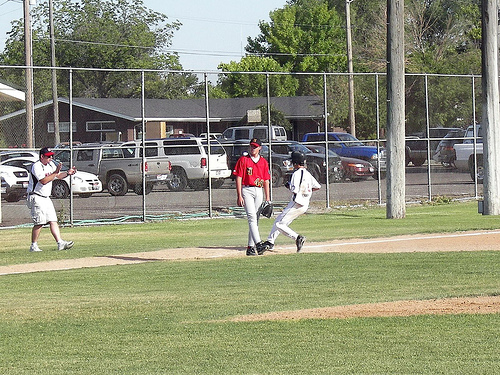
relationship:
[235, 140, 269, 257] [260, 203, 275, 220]
person playing with baseball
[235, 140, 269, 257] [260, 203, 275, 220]
player of baseball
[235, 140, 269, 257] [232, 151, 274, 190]
player wearing a red shirt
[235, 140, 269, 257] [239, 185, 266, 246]
player has a white pants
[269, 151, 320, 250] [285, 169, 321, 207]
player has a white shirt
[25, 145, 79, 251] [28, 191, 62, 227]
man wearing white shorts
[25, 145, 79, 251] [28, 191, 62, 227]
man wearing shorts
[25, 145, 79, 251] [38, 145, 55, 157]
man wearing blue and red cap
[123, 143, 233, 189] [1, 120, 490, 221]
car in parking lot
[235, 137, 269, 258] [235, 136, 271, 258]
person wearing red and white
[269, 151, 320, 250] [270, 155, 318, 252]
player wears white and black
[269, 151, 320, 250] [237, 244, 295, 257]
player arrives at base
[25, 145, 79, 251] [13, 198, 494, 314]
coach off field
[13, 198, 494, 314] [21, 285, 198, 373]
field has grass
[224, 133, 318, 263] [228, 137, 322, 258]
game of game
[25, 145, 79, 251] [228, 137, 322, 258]
coach for game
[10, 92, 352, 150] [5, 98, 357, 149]
cars by a building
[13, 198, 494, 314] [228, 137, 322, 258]
field for game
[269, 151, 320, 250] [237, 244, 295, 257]
runner reaches base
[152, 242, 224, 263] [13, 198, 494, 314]
pitcher's mound on a field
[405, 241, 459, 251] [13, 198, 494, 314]
dirt at a field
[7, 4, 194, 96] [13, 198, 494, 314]
tree by a field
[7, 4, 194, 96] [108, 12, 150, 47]
tree has leaves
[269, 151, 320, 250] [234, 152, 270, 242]
player in uniform